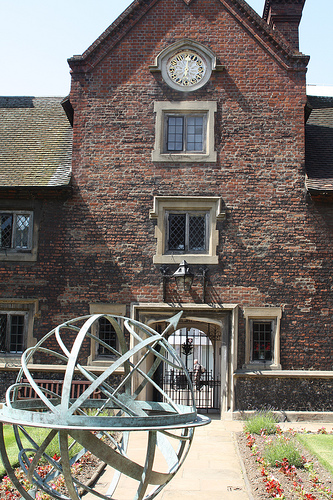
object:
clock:
[167, 49, 205, 87]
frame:
[149, 38, 228, 93]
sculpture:
[0, 310, 211, 500]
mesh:
[168, 213, 205, 251]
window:
[163, 208, 212, 258]